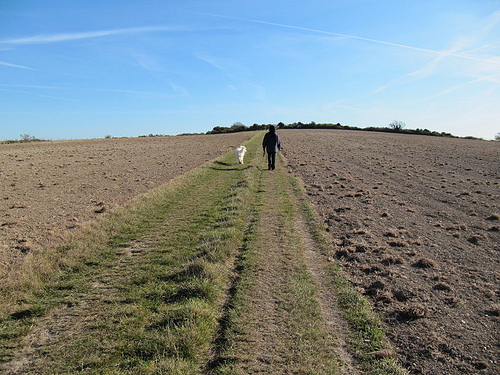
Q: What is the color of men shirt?
A: Black.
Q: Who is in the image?
A: Men and animal.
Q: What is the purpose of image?
A: Remembrance.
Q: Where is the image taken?
A: Forest.